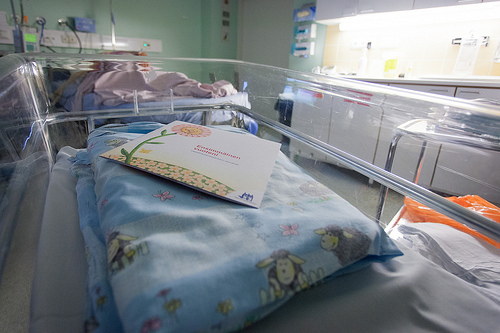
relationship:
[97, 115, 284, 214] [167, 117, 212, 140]
pamphlet with flower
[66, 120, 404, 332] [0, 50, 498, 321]
blanket in baby bed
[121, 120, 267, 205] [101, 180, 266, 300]
envelope on blanket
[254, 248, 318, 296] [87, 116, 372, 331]
sheep on blanket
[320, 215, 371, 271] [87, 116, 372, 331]
sheep on blanket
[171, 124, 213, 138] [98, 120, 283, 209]
flower on card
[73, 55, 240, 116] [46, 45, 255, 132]
blanket on bed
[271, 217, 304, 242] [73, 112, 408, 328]
butterfly on blanket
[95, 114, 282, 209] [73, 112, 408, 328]
card on blanket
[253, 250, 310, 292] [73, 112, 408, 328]
animal on blanket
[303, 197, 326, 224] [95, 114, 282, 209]
ground on card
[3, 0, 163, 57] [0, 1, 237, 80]
medical supplies on wall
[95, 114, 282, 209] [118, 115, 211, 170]
card with yellow flower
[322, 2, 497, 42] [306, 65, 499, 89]
lighting above counter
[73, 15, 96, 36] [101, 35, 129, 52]
equipment above light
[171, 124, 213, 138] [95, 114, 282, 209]
flower on card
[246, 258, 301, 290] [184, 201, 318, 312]
sheep on blanket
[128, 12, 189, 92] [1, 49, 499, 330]
light above baby bed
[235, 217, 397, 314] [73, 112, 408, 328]
sheep design on blanket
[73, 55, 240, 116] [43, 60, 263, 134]
blanket on hospital bed